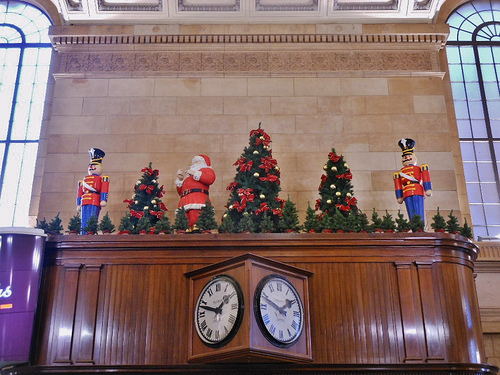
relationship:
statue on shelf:
[163, 148, 219, 228] [54, 220, 451, 372]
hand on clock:
[191, 291, 234, 323] [186, 268, 300, 324]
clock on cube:
[250, 251, 318, 359] [144, 234, 322, 370]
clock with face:
[185, 251, 317, 359] [190, 272, 244, 346]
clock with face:
[185, 251, 317, 359] [248, 268, 308, 352]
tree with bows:
[217, 122, 286, 231] [250, 199, 270, 216]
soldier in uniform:
[386, 127, 432, 229] [387, 165, 436, 224]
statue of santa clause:
[163, 148, 219, 228] [170, 150, 220, 220]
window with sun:
[0, 2, 56, 227] [3, 49, 33, 139]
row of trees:
[37, 203, 481, 244] [34, 213, 475, 243]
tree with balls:
[217, 122, 286, 231] [248, 132, 265, 184]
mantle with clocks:
[41, 234, 481, 373] [191, 276, 310, 349]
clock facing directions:
[190, 273, 244, 347] [186, 256, 313, 368]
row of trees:
[37, 203, 481, 244] [33, 211, 479, 250]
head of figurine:
[188, 148, 218, 178] [172, 146, 230, 235]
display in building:
[44, 130, 480, 242] [5, 5, 498, 372]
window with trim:
[443, 0, 499, 243] [443, 37, 496, 51]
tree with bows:
[217, 122, 286, 231] [234, 121, 284, 224]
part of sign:
[8, 242, 28, 273] [3, 231, 46, 365]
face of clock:
[263, 286, 295, 336] [250, 251, 318, 359]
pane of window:
[8, 46, 21, 138] [0, 2, 56, 227]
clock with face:
[250, 251, 318, 359] [259, 282, 300, 338]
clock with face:
[190, 273, 244, 347] [199, 283, 238, 340]